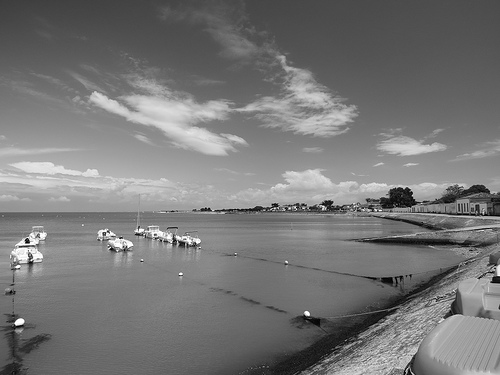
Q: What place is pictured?
A: It is a beach.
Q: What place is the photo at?
A: It is at the beach.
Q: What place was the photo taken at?
A: It was taken at the beach.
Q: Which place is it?
A: It is a beach.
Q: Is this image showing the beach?
A: Yes, it is showing the beach.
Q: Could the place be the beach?
A: Yes, it is the beach.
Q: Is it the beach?
A: Yes, it is the beach.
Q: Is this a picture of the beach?
A: Yes, it is showing the beach.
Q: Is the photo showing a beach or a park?
A: It is showing a beach.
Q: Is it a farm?
A: No, it is a beach.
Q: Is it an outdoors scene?
A: Yes, it is outdoors.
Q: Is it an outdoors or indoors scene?
A: It is outdoors.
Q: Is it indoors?
A: No, it is outdoors.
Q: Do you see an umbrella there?
A: No, there are no umbrellas.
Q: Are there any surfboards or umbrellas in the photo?
A: No, there are no umbrellas or surfboards.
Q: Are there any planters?
A: No, there are no planters.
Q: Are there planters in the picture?
A: No, there are no planters.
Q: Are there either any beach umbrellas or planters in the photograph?
A: No, there are no planters or beach umbrellas.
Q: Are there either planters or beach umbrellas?
A: No, there are no planters or beach umbrellas.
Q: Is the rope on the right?
A: Yes, the rope is on the right of the image.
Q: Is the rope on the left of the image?
A: No, the rope is on the right of the image.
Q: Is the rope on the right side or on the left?
A: The rope is on the right of the image.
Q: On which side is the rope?
A: The rope is on the right of the image.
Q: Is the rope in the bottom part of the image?
A: Yes, the rope is in the bottom of the image.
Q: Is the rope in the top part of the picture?
A: No, the rope is in the bottom of the image.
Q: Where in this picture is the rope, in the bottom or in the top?
A: The rope is in the bottom of the image.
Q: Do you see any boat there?
A: Yes, there is a boat.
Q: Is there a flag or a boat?
A: Yes, there is a boat.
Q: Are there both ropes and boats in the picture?
A: Yes, there are both a boat and a rope.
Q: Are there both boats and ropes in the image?
A: Yes, there are both a boat and a rope.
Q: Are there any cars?
A: No, there are no cars.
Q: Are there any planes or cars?
A: No, there are no cars or planes.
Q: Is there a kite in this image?
A: No, there are no kites.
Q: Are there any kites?
A: No, there are no kites.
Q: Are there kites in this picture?
A: No, there are no kites.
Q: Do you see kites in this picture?
A: No, there are no kites.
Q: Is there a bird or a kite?
A: No, there are no kites or birds.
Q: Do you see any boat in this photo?
A: Yes, there is a boat.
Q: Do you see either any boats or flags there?
A: Yes, there is a boat.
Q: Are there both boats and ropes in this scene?
A: Yes, there are both a boat and a rope.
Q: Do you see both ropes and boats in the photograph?
A: Yes, there are both a boat and a rope.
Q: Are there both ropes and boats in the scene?
A: Yes, there are both a boat and a rope.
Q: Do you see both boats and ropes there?
A: Yes, there are both a boat and a rope.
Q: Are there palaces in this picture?
A: No, there are no palaces.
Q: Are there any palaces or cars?
A: No, there are no palaces or cars.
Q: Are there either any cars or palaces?
A: No, there are no palaces or cars.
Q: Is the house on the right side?
A: Yes, the house is on the right of the image.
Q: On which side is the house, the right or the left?
A: The house is on the right of the image.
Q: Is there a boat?
A: Yes, there is a boat.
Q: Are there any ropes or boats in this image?
A: Yes, there is a boat.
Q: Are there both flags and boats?
A: No, there is a boat but no flags.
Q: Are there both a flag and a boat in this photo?
A: No, there is a boat but no flags.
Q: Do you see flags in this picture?
A: No, there are no flags.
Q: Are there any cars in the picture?
A: No, there are no cars.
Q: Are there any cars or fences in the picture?
A: No, there are no cars or fences.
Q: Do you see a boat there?
A: Yes, there is a boat.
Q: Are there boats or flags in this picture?
A: Yes, there is a boat.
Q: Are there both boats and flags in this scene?
A: No, there is a boat but no flags.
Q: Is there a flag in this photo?
A: No, there are no flags.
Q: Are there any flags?
A: No, there are no flags.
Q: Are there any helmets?
A: No, there are no helmets.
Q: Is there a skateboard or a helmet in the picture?
A: No, there are no helmets or skateboards.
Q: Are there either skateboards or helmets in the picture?
A: No, there are no helmets or skateboards.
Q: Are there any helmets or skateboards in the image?
A: No, there are no helmets or skateboards.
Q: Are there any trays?
A: No, there are no trays.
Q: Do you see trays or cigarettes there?
A: No, there are no trays or cigarettes.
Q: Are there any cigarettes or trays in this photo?
A: No, there are no trays or cigarettes.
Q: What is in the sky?
A: The clouds are in the sky.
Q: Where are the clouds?
A: The clouds are in the sky.